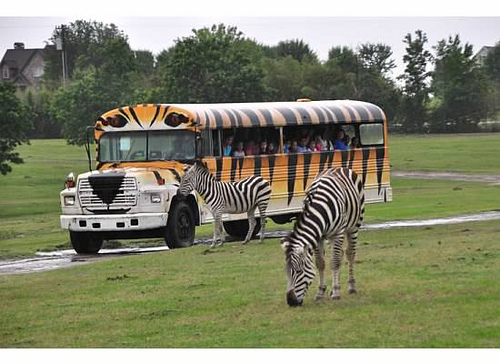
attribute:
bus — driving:
[56, 92, 396, 252]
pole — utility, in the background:
[44, 19, 91, 115]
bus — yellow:
[52, 96, 397, 264]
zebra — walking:
[175, 153, 274, 251]